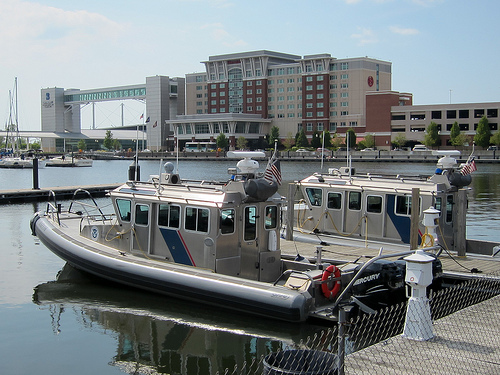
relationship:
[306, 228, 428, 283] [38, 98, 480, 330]
boardwalk to boats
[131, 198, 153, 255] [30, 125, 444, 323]
door on boat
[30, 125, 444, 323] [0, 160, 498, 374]
boat in water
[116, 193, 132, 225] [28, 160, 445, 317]
windows of boat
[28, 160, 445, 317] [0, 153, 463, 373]
boat in water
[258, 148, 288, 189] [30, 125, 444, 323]
flag on boat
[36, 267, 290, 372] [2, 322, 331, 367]
reflection on water